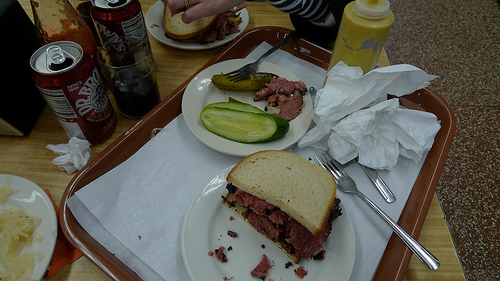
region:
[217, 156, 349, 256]
half of sandwich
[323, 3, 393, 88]
bottle of mustard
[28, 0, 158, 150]
drink cans on the table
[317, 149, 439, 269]
fork on the tray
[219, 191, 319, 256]
meat on the sandwich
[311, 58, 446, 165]
wadded up white napkins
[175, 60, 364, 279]
white plates on the tray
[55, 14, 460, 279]
brown tray on the table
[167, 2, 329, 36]
hand and arm of person eating a sandwich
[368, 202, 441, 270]
handle on the fork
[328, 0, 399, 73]
a bottle of mustard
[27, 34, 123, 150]
the can is open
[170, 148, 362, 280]
sandwich on a dish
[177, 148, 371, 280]
the dish is white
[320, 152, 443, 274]
fork on a tray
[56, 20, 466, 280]
tray is color brown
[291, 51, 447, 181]
a crumpled white napkin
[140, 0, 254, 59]
a sandwich on a dish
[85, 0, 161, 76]
the can is open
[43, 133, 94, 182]
a crumpled white paper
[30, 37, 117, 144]
open soda can sitting on table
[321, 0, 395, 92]
clear plastic mustard bottle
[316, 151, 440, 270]
silver metal fork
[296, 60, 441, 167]
two used white napkins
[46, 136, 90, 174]
used napkin folded into a ball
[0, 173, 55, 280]
white plate with food on it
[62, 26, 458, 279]
brown plastic tray containing food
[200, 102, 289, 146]
pickle slices on a white plate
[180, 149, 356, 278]
half of a sandwich sitting on a white plate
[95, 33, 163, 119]
clear glass containing soda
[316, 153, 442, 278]
the fork is color silver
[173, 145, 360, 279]
a sandwich on a dish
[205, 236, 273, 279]
crambs on white dish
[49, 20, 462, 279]
two dishes on tray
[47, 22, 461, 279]
tray is color brown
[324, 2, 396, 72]
a bottle of mustard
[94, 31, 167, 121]
glass with a drink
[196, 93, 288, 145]
two slices of pickles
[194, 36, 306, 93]
fork over a dish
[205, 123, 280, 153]
this is a sliced pickles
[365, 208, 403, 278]
this is some silverware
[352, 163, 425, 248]
this is a utensil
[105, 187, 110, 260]
the tray is plastic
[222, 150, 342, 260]
sandwich is cut in half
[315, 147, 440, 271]
fork rests next to sandwich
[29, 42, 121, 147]
can is open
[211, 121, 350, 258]
a sandwich on the plate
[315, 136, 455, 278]
fork on the tray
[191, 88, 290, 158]
a pickle ont he plate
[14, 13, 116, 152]
a can of soda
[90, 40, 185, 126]
a glass with ice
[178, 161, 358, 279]
white plate where sandwich is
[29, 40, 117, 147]
red coke on top of table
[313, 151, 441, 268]
metal fork next to white plate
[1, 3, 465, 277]
wooden table where tray is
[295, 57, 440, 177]
wrinkled white napkin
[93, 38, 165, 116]
glass full with ice and a little coke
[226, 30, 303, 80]
metal fork on top of pickle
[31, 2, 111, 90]
ketchup botle behind soda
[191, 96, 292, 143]
A slice of long dill pickle